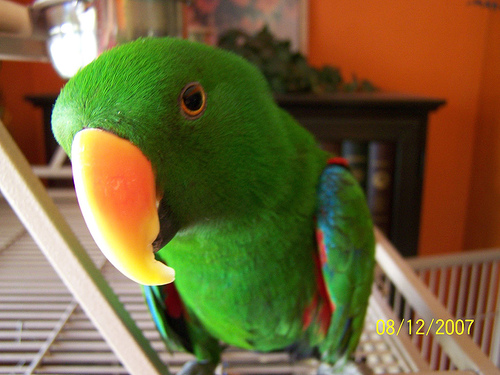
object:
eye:
[180, 83, 206, 116]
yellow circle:
[178, 83, 206, 116]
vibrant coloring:
[303, 155, 339, 338]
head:
[50, 36, 273, 287]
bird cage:
[0, 123, 495, 375]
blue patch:
[319, 165, 340, 266]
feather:
[315, 172, 362, 336]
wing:
[314, 165, 374, 370]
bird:
[50, 37, 376, 374]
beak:
[68, 126, 176, 287]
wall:
[0, 0, 500, 375]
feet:
[177, 345, 230, 375]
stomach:
[187, 255, 303, 345]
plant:
[208, 22, 381, 102]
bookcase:
[21, 89, 449, 260]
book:
[341, 135, 369, 203]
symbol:
[372, 169, 391, 191]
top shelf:
[19, 91, 450, 123]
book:
[369, 143, 392, 235]